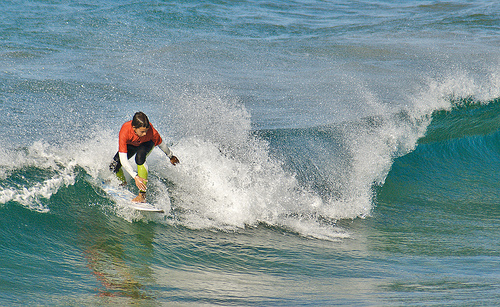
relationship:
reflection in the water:
[80, 208, 135, 300] [27, 18, 463, 288]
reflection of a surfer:
[80, 208, 135, 300] [106, 110, 188, 221]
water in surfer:
[0, 0, 499, 305] [106, 110, 188, 221]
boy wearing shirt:
[109, 110, 179, 203] [117, 120, 174, 180]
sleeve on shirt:
[156, 140, 174, 161] [117, 120, 174, 180]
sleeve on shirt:
[120, 152, 138, 182] [117, 120, 174, 180]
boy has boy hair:
[109, 110, 179, 203] [128, 110, 151, 129]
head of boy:
[129, 110, 151, 140] [109, 110, 179, 203]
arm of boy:
[118, 124, 139, 184] [109, 110, 179, 203]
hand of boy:
[167, 151, 180, 168] [109, 110, 179, 203]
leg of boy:
[131, 139, 152, 202] [109, 110, 179, 203]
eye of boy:
[137, 128, 146, 136] [109, 110, 179, 203]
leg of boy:
[131, 139, 151, 195] [109, 110, 179, 203]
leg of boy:
[108, 148, 133, 191] [109, 110, 179, 203]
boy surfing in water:
[109, 110, 179, 203] [0, 1, 498, 303]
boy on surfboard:
[109, 110, 179, 203] [98, 179, 163, 213]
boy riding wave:
[109, 110, 179, 203] [1, 73, 498, 304]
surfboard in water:
[103, 184, 163, 214] [0, 1, 498, 303]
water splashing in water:
[0, 20, 262, 160] [0, 0, 499, 305]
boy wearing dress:
[108, 100, 172, 222] [110, 110, 162, 168]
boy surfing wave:
[109, 110, 179, 203] [44, 93, 461, 227]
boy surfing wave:
[109, 110, 179, 203] [7, 93, 451, 252]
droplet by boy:
[193, 107, 235, 139] [109, 110, 179, 203]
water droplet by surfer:
[246, 139, 267, 152] [108, 109, 182, 202]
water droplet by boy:
[230, 91, 259, 111] [109, 110, 179, 203]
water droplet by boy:
[11, 91, 29, 104] [109, 110, 179, 203]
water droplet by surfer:
[71, 75, 102, 92] [108, 109, 182, 202]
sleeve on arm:
[156, 140, 174, 161] [155, 126, 178, 156]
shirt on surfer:
[115, 119, 161, 152] [110, 105, 180, 200]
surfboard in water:
[103, 186, 163, 215] [19, 215, 480, 305]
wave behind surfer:
[1, 17, 494, 243] [108, 109, 182, 202]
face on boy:
[133, 118, 152, 144] [109, 110, 179, 203]